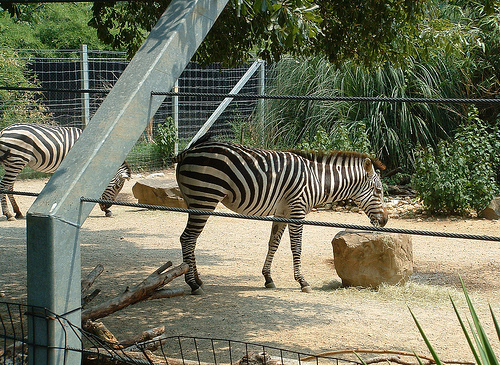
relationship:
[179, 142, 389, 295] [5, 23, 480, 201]
zebra in zoo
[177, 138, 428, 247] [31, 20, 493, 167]
zebra in habitat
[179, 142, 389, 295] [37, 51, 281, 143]
zebra in enclosure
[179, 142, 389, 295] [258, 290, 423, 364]
zebra in dirt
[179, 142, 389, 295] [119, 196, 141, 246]
zebra facing down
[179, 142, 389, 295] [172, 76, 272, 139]
zebra behind fence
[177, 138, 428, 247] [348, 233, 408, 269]
zebra standing by rock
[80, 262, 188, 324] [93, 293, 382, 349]
logs on ground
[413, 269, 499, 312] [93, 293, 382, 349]
hay on ground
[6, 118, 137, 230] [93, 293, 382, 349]
zebra touching ground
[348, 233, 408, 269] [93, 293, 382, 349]
rock on ground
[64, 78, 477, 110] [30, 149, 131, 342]
wires inside beam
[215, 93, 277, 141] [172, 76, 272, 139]
sticks beside fence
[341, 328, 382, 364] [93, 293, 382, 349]
object on ground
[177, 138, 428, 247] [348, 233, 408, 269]
zebra over rock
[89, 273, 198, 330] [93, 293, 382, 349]
logs on ground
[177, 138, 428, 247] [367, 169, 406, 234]
zebra has head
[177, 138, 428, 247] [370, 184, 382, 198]
zebra has eye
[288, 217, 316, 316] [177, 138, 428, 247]
leg of zebra